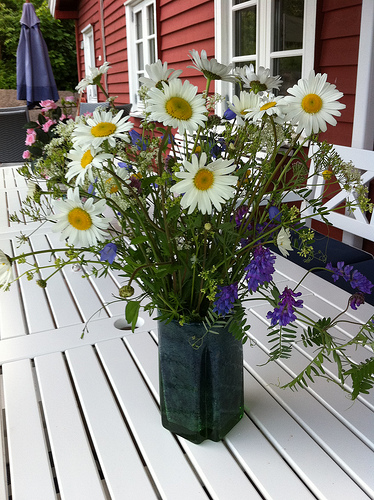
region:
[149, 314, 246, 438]
a vase sitting on the middle of the table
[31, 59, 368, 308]
the white daisies sitting in the vase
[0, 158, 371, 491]
the table the flowers are sitting on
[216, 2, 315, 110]
some of the windows of the house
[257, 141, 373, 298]
a bench sitting next to the table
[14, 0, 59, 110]
a blue umbrella off to the side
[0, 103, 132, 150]
some chairs sitting next to the table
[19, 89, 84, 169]
some pink flowers sitting on the table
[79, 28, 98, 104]
the door leading to the patio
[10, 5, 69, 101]
the umbrella is closed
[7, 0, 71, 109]
the umbrella is purple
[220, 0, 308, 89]
the window on the house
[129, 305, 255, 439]
the vase on the table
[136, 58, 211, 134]
white flowers in the vase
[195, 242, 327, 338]
purple flowers in the vase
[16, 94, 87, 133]
the pink flowers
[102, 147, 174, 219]
small white flowers in the vase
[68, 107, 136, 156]
The flower is white and yellow.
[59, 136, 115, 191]
The flower is white and yellow.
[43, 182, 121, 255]
The flower is white and yellow.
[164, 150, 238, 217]
The flower is white and yellow.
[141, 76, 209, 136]
The flower is white and yellow.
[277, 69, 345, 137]
The flower is white and yellow.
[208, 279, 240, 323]
The flower is purple.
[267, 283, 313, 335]
The flower is purple.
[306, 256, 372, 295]
The flower is purple.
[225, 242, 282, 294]
The flower is purple.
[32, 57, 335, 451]
Wildflowers in a blue vase.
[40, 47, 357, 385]
Beautiful bouquet of wildflowers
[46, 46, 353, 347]
A bunch of daisies in a vase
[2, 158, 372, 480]
White table holding a vase of flowers.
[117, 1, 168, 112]
House windows with white trim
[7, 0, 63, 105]
Blue umbrella used for a table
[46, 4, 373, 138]
Red house with white trim door and windows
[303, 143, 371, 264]
White picnic bench that matches the table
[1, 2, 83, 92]
Green trees beside a red house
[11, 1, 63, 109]
Big umbrella that provides shade in the sun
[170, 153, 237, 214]
White flower in flower vase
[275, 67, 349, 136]
White flower in flower vase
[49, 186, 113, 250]
White flower in flower vase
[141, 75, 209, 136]
White flower in flower vase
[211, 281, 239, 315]
Flower bulb in flower vase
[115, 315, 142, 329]
Hole in white table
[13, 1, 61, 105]
Purple umbrella in front of window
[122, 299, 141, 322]
Small green leaf near purple flower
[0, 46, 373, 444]
Flower vase on white table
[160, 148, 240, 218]
a yellow and white daisy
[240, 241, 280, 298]
purple petals on a flower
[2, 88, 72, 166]
a group of pink flowers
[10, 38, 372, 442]
a bouquet of flowers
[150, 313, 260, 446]
a dark blue vase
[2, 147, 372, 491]
a long white table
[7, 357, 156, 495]
planks on the table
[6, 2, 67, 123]
a umbrella on the side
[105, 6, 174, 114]
window on the building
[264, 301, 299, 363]
leaf on the flower